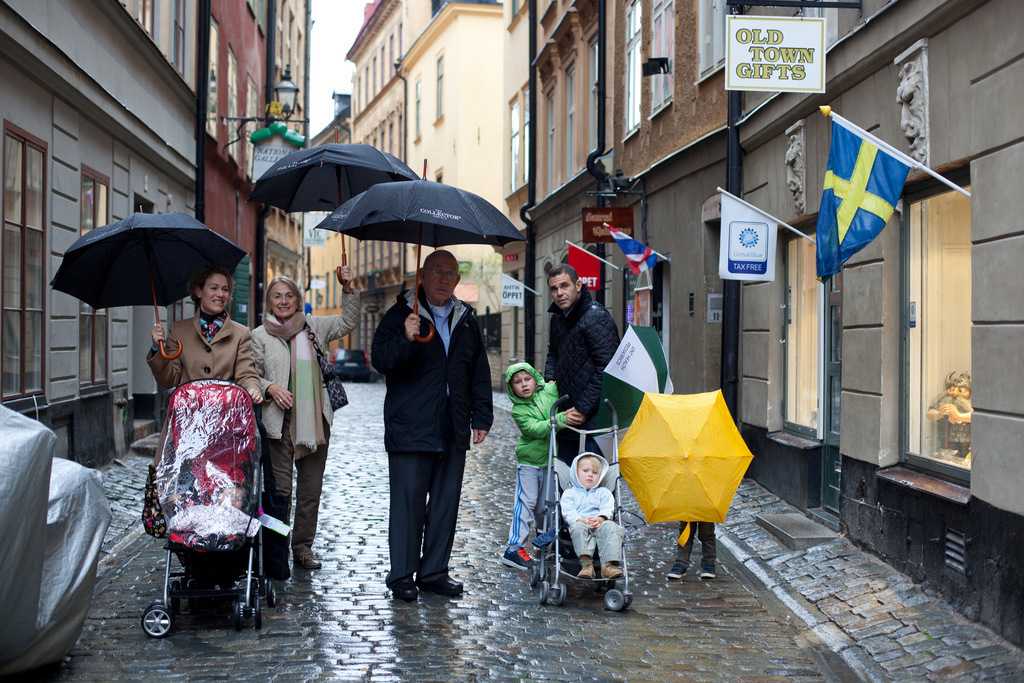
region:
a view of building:
[381, 76, 479, 152]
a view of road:
[332, 597, 431, 658]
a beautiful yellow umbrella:
[618, 391, 774, 589]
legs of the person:
[367, 435, 494, 578]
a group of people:
[224, 114, 876, 674]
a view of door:
[885, 190, 988, 443]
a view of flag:
[708, 157, 819, 456]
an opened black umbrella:
[49, 211, 245, 309]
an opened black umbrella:
[237, 143, 424, 219]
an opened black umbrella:
[315, 178, 531, 248]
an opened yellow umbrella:
[616, 390, 750, 528]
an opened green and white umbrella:
[601, 323, 672, 434]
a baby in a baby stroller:
[139, 375, 280, 633]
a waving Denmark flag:
[811, 122, 906, 281]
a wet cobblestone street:
[38, 377, 838, 679]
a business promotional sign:
[721, 17, 830, 93]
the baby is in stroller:
[552, 431, 670, 628]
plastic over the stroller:
[162, 386, 295, 662]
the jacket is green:
[514, 405, 544, 460]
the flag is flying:
[561, 193, 935, 282]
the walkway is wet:
[491, 570, 910, 670]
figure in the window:
[928, 367, 963, 453]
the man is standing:
[397, 217, 478, 614]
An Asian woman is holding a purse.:
[589, 509, 602, 530]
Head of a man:
[417, 250, 463, 301]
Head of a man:
[544, 256, 595, 311]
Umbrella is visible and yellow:
[613, 379, 749, 535]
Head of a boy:
[572, 445, 605, 491]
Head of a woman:
[199, 269, 235, 320]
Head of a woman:
[265, 274, 303, 325]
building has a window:
[0, 131, 25, 223]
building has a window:
[1, 221, 21, 305]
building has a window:
[23, 227, 43, 310]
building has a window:
[30, 309, 44, 389]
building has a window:
[1, 311, 25, 397]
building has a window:
[83, 318, 93, 392]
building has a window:
[96, 306, 109, 383]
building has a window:
[779, 236, 824, 433]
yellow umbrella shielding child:
[613, 388, 754, 532]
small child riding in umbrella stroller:
[536, 389, 636, 615]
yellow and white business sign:
[720, 10, 831, 99]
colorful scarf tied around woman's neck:
[259, 309, 330, 456]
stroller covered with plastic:
[142, 377, 275, 640]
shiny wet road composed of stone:
[33, 371, 1020, 679]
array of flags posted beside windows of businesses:
[488, 102, 975, 312]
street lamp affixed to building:
[270, 64, 300, 118]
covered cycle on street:
[0, 406, 119, 679]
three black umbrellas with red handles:
[48, 138, 532, 316]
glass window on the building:
[902, 182, 975, 473]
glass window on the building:
[649, 0, 672, 103]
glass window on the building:
[620, 0, 639, 133]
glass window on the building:
[588, 26, 596, 148]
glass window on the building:
[17, 127, 41, 394]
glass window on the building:
[77, 171, 104, 377]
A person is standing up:
[362, 247, 490, 603]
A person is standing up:
[246, 258, 352, 569]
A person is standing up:
[149, 273, 217, 410]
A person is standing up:
[527, 236, 645, 417]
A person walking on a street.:
[347, 250, 502, 601]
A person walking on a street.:
[233, 269, 374, 570]